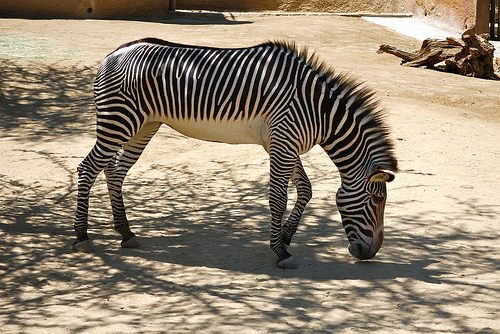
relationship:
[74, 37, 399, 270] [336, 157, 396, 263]
zebra has head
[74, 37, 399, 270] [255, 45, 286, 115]
zebra has stripe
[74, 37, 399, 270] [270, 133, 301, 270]
zebra has leg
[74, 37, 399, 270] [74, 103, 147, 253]
zebra has leg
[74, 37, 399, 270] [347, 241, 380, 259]
zebra has nose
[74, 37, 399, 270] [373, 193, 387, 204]
zebra has eye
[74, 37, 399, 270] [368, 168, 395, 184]
zebra has ear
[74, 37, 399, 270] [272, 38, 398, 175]
zebra has mane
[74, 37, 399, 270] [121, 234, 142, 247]
zebra has hoof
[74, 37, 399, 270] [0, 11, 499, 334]
zebra in field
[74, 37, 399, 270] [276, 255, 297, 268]
zebra has hoof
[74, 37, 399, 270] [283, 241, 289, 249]
zebra has hoof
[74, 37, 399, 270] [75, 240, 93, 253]
zebra has hoof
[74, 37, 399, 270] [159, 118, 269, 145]
zebra has belly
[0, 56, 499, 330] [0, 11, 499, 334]
shadow on field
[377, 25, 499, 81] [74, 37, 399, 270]
wood behind zebra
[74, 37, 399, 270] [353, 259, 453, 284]
zebra has shadow